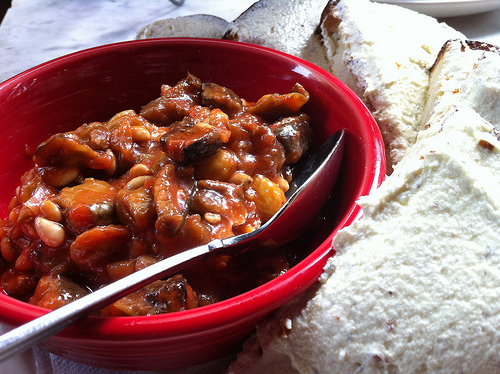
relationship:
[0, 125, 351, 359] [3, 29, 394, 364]
spoon in a bowl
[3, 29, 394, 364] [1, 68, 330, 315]
bowl with food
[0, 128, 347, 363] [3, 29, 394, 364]
spoon in a bowl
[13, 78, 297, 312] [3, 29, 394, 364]
food on side of a bowl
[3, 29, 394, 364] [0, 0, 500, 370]
bowl on a table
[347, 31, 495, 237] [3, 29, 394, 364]
bread near a bowl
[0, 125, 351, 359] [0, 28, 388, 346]
spoon in dish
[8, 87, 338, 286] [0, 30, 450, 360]
chili in bowl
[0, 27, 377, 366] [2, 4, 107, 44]
stuff on table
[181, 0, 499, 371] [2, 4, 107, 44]
stuff on table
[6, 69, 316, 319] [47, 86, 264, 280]
vegetables in chili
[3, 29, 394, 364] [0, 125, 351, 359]
bowl and spoon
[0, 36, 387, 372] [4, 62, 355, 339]
bowl with food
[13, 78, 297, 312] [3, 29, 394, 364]
food in bowl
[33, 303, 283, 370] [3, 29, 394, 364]
side on bowl